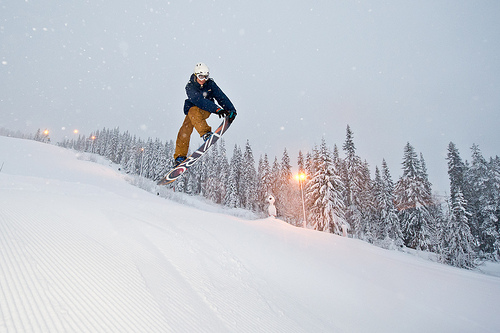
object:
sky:
[0, 1, 500, 194]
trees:
[302, 135, 352, 237]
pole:
[299, 180, 307, 228]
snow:
[0, 137, 500, 333]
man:
[173, 61, 237, 167]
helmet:
[194, 63, 209, 76]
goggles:
[194, 71, 210, 81]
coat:
[183, 74, 239, 115]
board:
[156, 111, 238, 186]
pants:
[173, 106, 211, 160]